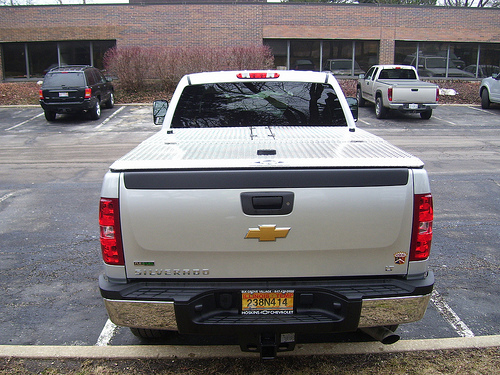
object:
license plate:
[241, 289, 295, 314]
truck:
[97, 71, 436, 367]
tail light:
[99, 197, 125, 265]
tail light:
[409, 192, 433, 262]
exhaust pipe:
[360, 327, 400, 345]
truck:
[356, 65, 440, 120]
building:
[2, 0, 500, 88]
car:
[38, 65, 115, 122]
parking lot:
[0, 102, 499, 355]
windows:
[0, 39, 118, 82]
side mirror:
[153, 100, 169, 125]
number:
[247, 298, 288, 307]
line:
[96, 318, 117, 346]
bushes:
[102, 46, 276, 93]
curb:
[0, 335, 500, 358]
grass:
[2, 351, 499, 374]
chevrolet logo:
[244, 223, 291, 242]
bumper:
[97, 275, 434, 329]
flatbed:
[98, 125, 433, 283]